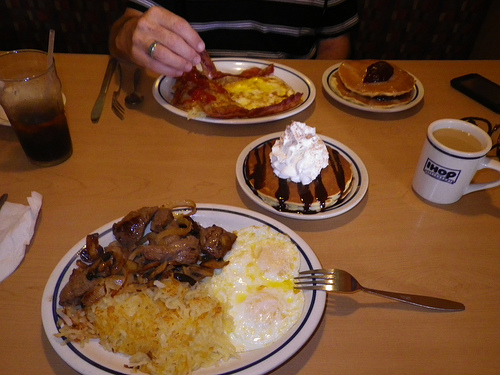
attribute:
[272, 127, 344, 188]
cream — whipped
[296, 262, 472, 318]
fork — silver, metal 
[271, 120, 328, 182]
cream — whipped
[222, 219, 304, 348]
eggs — RUNNY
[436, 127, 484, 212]
cup — coffee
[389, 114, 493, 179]
cup — white